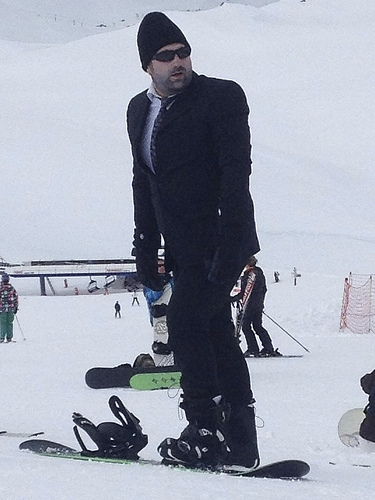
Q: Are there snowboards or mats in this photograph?
A: Yes, there is a snowboard.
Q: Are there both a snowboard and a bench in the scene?
A: No, there is a snowboard but no benches.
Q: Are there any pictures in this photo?
A: No, there are no pictures.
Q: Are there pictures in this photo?
A: No, there are no pictures.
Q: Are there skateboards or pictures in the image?
A: No, there are no pictures or skateboards.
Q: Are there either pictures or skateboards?
A: No, there are no pictures or skateboards.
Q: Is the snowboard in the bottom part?
A: Yes, the snowboard is in the bottom of the image.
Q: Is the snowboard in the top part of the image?
A: No, the snowboard is in the bottom of the image.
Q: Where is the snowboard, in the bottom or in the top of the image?
A: The snowboard is in the bottom of the image.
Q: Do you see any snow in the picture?
A: Yes, there is snow.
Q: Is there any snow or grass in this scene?
A: Yes, there is snow.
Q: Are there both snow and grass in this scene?
A: No, there is snow but no grass.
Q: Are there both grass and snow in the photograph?
A: No, there is snow but no grass.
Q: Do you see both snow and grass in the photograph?
A: No, there is snow but no grass.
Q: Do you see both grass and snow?
A: No, there is snow but no grass.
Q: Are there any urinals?
A: No, there are no urinals.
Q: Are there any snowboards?
A: Yes, there is a snowboard.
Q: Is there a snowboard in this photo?
A: Yes, there is a snowboard.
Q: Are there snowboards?
A: Yes, there is a snowboard.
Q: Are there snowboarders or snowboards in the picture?
A: Yes, there is a snowboard.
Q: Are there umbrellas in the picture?
A: No, there are no umbrellas.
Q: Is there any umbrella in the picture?
A: No, there are no umbrellas.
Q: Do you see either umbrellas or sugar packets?
A: No, there are no umbrellas or sugar packets.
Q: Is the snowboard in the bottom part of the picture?
A: Yes, the snowboard is in the bottom of the image.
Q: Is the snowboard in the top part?
A: No, the snowboard is in the bottom of the image.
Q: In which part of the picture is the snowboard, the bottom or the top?
A: The snowboard is in the bottom of the image.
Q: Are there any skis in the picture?
A: Yes, there are skis.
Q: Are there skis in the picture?
A: Yes, there are skis.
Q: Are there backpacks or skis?
A: Yes, there are skis.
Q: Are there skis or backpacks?
A: Yes, there are skis.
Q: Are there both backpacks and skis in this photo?
A: No, there are skis but no backpacks.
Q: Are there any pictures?
A: No, there are no pictures.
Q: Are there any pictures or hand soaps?
A: No, there are no pictures or hand soaps.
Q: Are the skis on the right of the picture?
A: Yes, the skis are on the right of the image.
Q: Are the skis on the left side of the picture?
A: No, the skis are on the right of the image.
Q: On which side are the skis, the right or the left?
A: The skis are on the right of the image.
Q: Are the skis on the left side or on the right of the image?
A: The skis are on the right of the image.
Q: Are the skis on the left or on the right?
A: The skis are on the right of the image.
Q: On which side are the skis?
A: The skis are on the right of the image.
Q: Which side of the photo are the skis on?
A: The skis are on the right of the image.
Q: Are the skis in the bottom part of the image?
A: Yes, the skis are in the bottom of the image.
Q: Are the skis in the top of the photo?
A: No, the skis are in the bottom of the image.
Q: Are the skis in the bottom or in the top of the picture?
A: The skis are in the bottom of the image.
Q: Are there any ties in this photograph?
A: Yes, there is a tie.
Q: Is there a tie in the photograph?
A: Yes, there is a tie.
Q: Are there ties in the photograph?
A: Yes, there is a tie.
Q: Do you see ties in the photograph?
A: Yes, there is a tie.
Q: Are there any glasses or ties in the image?
A: Yes, there is a tie.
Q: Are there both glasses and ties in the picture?
A: Yes, there are both a tie and glasses.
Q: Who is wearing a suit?
A: The man is wearing a suit.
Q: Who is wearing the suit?
A: The man is wearing a suit.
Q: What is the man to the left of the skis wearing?
A: The man is wearing a suit.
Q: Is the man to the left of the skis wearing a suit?
A: Yes, the man is wearing a suit.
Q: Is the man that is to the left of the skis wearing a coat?
A: No, the man is wearing a suit.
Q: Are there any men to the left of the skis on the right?
A: Yes, there is a man to the left of the skis.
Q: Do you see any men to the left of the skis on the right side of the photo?
A: Yes, there is a man to the left of the skis.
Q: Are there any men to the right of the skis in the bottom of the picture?
A: No, the man is to the left of the skis.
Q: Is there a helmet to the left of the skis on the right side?
A: No, there is a man to the left of the skis.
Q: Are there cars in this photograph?
A: No, there are no cars.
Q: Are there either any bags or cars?
A: No, there are no cars or bags.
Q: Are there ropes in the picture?
A: No, there are no ropes.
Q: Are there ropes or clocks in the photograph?
A: No, there are no ropes or clocks.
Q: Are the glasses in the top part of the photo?
A: Yes, the glasses are in the top of the image.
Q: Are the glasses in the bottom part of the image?
A: No, the glasses are in the top of the image.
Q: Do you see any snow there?
A: Yes, there is snow.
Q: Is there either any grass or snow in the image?
A: Yes, there is snow.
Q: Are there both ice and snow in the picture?
A: No, there is snow but no ice.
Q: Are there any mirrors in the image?
A: No, there are no mirrors.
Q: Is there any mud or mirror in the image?
A: No, there are no mirrors or mud.